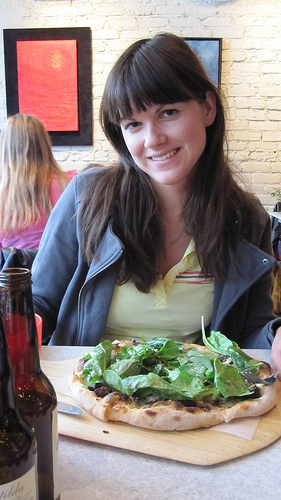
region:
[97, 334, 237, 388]
pile of green vegetables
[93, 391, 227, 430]
the pizza crust edge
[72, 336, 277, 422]
the whole pizza intact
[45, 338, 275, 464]
the wooden serving board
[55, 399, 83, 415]
the edge of a butter knife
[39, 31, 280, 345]
the woman posing with the pizza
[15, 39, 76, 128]
the red picture on the wall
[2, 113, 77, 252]
the blond haired woman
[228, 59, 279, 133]
the yellow brick wall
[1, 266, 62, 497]
the two brown bottles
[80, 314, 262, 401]
Green spinach on a pizza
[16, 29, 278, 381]
Girl with long dark hair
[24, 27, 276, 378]
Girl wearing a blue jacket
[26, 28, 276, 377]
Girl wearing a yellow shirt with stripes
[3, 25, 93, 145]
Red painting with a black frame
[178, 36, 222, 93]
Blue picture with a black fram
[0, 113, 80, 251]
Girl with long blonde hair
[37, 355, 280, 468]
Wooden cutting board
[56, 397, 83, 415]
Butter knife lying on a cutting board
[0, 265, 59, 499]
Half empty glass bottle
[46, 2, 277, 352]
Woman looking at the camera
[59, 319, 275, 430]
Pizza in front of the woman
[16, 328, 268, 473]
The pizza is on a paddle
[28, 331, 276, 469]
Pizza paddle made of wood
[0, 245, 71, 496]
Bottles of beer to the left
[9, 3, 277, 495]
Photo taken during the day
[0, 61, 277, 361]
Two people pictured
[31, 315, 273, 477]
Pizza paddle on the table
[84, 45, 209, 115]
The woman has bangs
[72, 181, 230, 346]
Yellow shirt on the woman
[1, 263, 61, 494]
Two glass liquor bottles.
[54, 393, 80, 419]
Front part of a knife.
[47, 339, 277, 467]
Wood serving board.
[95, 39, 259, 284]
Woman with long hair.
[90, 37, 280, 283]
Woman with dark hair.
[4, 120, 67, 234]
Woman with long blonde hair.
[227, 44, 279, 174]
White brick wall.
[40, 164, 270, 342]
Blue long sleeve jacket.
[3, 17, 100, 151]
Wide black picture frame on left.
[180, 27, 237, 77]
Black picture frame on right.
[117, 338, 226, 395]
a pile of lettuce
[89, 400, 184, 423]
crust of a pizza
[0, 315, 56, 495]
two bottles of beer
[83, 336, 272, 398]
purple and green lettuce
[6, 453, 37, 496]
label on a beer bottle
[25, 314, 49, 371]
a small red cup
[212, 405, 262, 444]
napkin under a pizza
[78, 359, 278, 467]
wooden cutting board with pizza on it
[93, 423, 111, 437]
a small crumb on wood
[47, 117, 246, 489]
woman getting ready to eat pizza